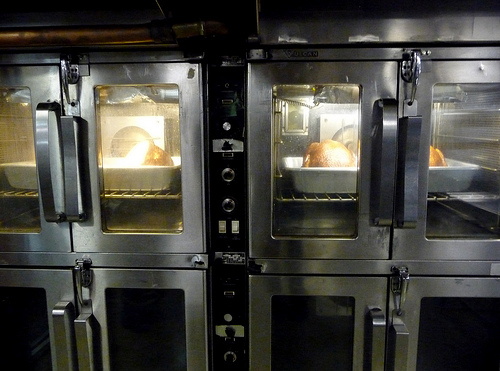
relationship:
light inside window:
[267, 86, 407, 221] [276, 85, 356, 206]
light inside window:
[267, 86, 407, 221] [91, 84, 183, 237]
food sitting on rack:
[280, 138, 356, 207] [293, 172, 473, 212]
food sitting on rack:
[280, 138, 356, 207] [3, 185, 227, 210]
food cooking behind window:
[278, 131, 480, 201] [265, 67, 499, 254]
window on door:
[276, 85, 356, 206] [69, 93, 223, 301]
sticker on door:
[284, 47, 320, 59] [57, 85, 234, 333]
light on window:
[95, 100, 176, 117] [1, 87, 44, 237]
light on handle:
[63, 69, 207, 209] [33, 121, 96, 242]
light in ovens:
[119, 148, 146, 165] [4, 35, 500, 371]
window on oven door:
[70, 62, 194, 239] [0, 60, 205, 261]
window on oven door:
[263, 75, 363, 241] [247, 49, 487, 258]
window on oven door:
[100, 277, 191, 367] [2, 267, 207, 367]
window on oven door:
[265, 284, 357, 369] [247, 267, 488, 367]